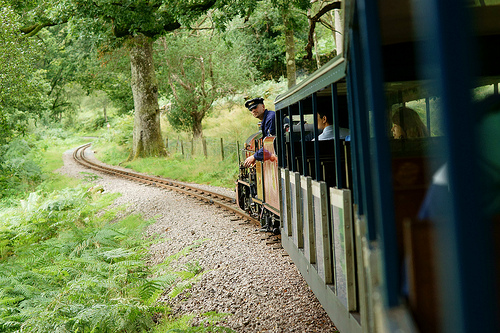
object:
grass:
[0, 73, 500, 333]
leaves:
[106, 2, 116, 13]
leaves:
[0, 49, 11, 59]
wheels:
[271, 227, 281, 236]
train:
[234, 0, 500, 333]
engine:
[233, 120, 281, 236]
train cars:
[273, 1, 500, 333]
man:
[308, 104, 352, 141]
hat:
[244, 98, 265, 112]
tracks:
[71, 141, 281, 239]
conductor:
[241, 97, 289, 170]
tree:
[0, 0, 236, 167]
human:
[389, 106, 429, 141]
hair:
[391, 105, 431, 138]